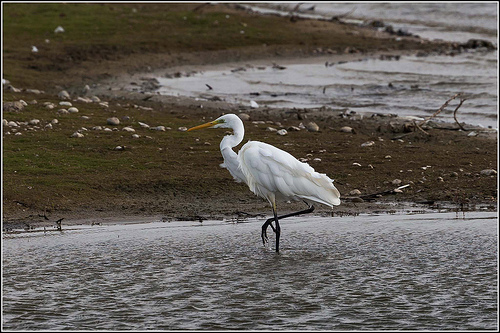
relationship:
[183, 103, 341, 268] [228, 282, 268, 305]
bird in water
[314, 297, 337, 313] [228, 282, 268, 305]
ice in water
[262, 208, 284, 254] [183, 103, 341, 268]
leg of bird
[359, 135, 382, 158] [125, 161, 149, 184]
rock on grass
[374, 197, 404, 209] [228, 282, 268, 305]
mud near water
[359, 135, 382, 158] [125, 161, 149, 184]
rocks on grass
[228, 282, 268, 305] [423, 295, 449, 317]
water has waves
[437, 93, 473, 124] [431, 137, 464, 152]
branches on shore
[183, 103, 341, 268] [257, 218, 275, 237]
bird has claw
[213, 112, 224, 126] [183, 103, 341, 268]
eye of bird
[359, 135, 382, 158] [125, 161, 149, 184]
rocks in grass